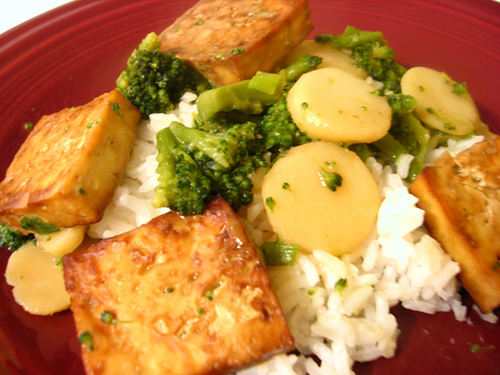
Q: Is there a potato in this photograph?
A: Yes, there is a potato.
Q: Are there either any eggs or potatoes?
A: Yes, there is a potato.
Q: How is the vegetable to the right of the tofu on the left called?
A: The vegetable is a potato.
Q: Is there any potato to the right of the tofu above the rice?
A: Yes, there is a potato to the right of the tofu.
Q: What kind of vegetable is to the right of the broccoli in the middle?
A: The vegetable is a potato.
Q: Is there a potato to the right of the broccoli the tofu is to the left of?
A: Yes, there is a potato to the right of the broccoli.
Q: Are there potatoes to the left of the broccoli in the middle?
A: No, the potato is to the right of the broccoli.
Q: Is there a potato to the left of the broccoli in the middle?
A: No, the potato is to the right of the broccoli.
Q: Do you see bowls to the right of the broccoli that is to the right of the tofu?
A: No, there is a potato to the right of the broccoli.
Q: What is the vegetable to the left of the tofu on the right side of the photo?
A: The vegetable is a potato.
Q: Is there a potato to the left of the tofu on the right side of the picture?
A: Yes, there is a potato to the left of the tofu.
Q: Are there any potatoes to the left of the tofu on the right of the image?
A: Yes, there is a potato to the left of the tofu.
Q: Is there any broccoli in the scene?
A: Yes, there is broccoli.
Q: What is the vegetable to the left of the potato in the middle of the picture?
A: The vegetable is broccoli.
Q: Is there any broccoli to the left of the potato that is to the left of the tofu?
A: Yes, there is broccoli to the left of the potato.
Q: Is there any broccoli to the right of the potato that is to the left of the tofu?
A: No, the broccoli is to the left of the potato.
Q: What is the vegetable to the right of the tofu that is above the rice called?
A: The vegetable is broccoli.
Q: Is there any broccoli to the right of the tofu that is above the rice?
A: Yes, there is broccoli to the right of the tofu.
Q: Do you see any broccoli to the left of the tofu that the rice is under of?
A: No, the broccoli is to the right of the tofu.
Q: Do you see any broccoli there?
A: Yes, there is broccoli.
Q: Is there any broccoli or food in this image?
A: Yes, there is broccoli.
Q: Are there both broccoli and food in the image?
A: Yes, there are both broccoli and food.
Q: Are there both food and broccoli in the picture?
A: Yes, there are both broccoli and food.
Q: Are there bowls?
A: No, there are no bowls.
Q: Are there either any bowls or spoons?
A: No, there are no bowls or spoons.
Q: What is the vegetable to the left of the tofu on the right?
A: The vegetable is broccoli.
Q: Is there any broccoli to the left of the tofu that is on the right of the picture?
A: Yes, there is broccoli to the left of the tofu.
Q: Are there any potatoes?
A: Yes, there is a potato.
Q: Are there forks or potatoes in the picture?
A: Yes, there is a potato.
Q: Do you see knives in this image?
A: No, there are no knives.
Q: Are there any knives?
A: No, there are no knives.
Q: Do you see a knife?
A: No, there are no knives.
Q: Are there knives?
A: No, there are no knives.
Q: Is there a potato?
A: Yes, there is a potato.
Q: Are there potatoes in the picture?
A: Yes, there is a potato.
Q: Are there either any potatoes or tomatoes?
A: Yes, there is a potato.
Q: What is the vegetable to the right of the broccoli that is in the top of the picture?
A: The vegetable is a potato.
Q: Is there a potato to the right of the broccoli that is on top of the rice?
A: Yes, there is a potato to the right of the broccoli.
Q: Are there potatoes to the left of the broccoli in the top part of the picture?
A: No, the potato is to the right of the broccoli.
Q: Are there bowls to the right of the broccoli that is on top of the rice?
A: No, there is a potato to the right of the broccoli.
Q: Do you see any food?
A: Yes, there is food.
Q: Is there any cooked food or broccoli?
A: Yes, there is cooked food.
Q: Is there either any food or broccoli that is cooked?
A: Yes, the food is cooked.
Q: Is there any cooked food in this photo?
A: Yes, there is cooked food.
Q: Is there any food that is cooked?
A: Yes, there is food that is cooked.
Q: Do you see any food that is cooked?
A: Yes, there is food that is cooked.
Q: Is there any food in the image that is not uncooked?
A: Yes, there is cooked food.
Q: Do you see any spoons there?
A: No, there are no spoons.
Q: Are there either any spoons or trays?
A: No, there are no spoons or trays.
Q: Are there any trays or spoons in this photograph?
A: No, there are no spoons or trays.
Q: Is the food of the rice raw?
A: No, the food is cooked.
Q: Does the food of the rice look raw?
A: No, the food is cooked.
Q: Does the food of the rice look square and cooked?
A: Yes, the food is square and cooked.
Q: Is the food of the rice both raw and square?
A: No, the food is square but cooked.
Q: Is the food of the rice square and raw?
A: No, the food is square but cooked.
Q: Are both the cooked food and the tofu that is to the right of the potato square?
A: Yes, both the food and the tofu are square.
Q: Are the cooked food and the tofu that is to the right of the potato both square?
A: Yes, both the food and the tofu are square.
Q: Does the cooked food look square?
A: Yes, the food is square.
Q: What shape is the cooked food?
A: The food is square.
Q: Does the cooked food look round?
A: No, the food is square.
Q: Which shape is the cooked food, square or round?
A: The food is square.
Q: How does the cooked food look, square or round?
A: The food is square.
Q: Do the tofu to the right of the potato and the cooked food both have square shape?
A: Yes, both the tofu and the food are square.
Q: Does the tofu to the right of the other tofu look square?
A: Yes, the tofu is square.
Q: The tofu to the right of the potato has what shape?
A: The tofu is square.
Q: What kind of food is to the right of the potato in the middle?
A: The food is tofu.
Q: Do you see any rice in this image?
A: Yes, there is rice.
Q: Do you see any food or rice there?
A: Yes, there is rice.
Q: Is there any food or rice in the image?
A: Yes, there is rice.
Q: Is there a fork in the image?
A: No, there are no forks.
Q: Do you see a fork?
A: No, there are no forks.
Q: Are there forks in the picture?
A: No, there are no forks.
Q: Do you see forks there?
A: No, there are no forks.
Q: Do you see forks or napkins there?
A: No, there are no forks or napkins.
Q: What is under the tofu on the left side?
A: The rice is under the tofu.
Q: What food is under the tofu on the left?
A: The food is rice.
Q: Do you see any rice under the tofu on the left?
A: Yes, there is rice under the tofu.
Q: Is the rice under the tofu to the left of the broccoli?
A: Yes, the rice is under the tofu.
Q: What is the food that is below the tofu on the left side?
A: The food is rice.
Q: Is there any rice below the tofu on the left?
A: Yes, there is rice below the tofu.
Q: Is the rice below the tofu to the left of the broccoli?
A: Yes, the rice is below the tofu.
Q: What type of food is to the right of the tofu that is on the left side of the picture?
A: The food is rice.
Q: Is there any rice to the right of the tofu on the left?
A: Yes, there is rice to the right of the tofu.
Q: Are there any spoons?
A: No, there are no spoons.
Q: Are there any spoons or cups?
A: No, there are no spoons or cups.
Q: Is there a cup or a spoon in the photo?
A: No, there are no spoons or cups.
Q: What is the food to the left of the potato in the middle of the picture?
A: The food is tofu.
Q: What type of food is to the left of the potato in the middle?
A: The food is tofu.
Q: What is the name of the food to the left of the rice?
A: The food is tofu.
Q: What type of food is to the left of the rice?
A: The food is tofu.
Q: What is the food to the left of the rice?
A: The food is tofu.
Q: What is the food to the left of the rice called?
A: The food is tofu.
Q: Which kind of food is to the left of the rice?
A: The food is tofu.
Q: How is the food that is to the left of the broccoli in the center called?
A: The food is tofu.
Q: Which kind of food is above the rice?
A: The food is tofu.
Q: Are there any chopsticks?
A: No, there are no chopsticks.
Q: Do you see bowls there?
A: No, there are no bowls.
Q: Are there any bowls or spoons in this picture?
A: No, there are no bowls or spoons.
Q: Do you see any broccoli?
A: Yes, there is broccoli.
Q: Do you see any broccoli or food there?
A: Yes, there is broccoli.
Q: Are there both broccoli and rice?
A: Yes, there are both broccoli and rice.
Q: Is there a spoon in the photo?
A: No, there are no spoons.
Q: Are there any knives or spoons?
A: No, there are no spoons or knives.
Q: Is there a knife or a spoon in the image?
A: No, there are no spoons or knives.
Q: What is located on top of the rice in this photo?
A: The broccoli is on top of the rice.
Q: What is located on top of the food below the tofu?
A: The broccoli is on top of the rice.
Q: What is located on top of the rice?
A: The broccoli is on top of the rice.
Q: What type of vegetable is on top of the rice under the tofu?
A: The vegetable is broccoli.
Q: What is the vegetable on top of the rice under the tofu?
A: The vegetable is broccoli.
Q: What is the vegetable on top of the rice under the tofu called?
A: The vegetable is broccoli.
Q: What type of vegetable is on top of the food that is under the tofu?
A: The vegetable is broccoli.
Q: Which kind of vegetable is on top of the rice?
A: The vegetable is broccoli.